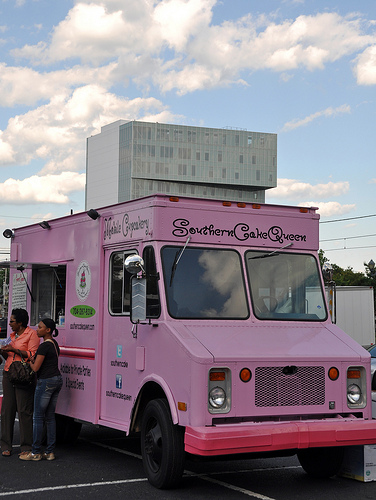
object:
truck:
[1, 193, 375, 491]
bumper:
[182, 415, 375, 458]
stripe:
[56, 345, 96, 359]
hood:
[167, 322, 372, 363]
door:
[94, 240, 140, 427]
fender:
[155, 320, 192, 429]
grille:
[251, 361, 327, 410]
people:
[17, 311, 67, 465]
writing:
[170, 215, 309, 245]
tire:
[134, 395, 186, 491]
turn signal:
[238, 365, 253, 384]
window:
[26, 262, 69, 328]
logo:
[73, 258, 93, 304]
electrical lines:
[319, 213, 376, 229]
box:
[339, 445, 375, 483]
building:
[251, 285, 375, 348]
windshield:
[156, 240, 254, 326]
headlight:
[206, 383, 230, 411]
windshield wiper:
[247, 242, 292, 261]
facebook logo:
[114, 373, 125, 390]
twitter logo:
[115, 343, 124, 359]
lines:
[0, 441, 302, 498]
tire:
[296, 446, 344, 478]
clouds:
[0, 2, 374, 205]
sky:
[0, 0, 376, 274]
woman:
[0, 304, 41, 458]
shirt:
[3, 326, 43, 377]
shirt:
[35, 336, 65, 381]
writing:
[102, 213, 150, 242]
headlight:
[344, 380, 364, 406]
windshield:
[241, 247, 332, 325]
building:
[80, 112, 282, 210]